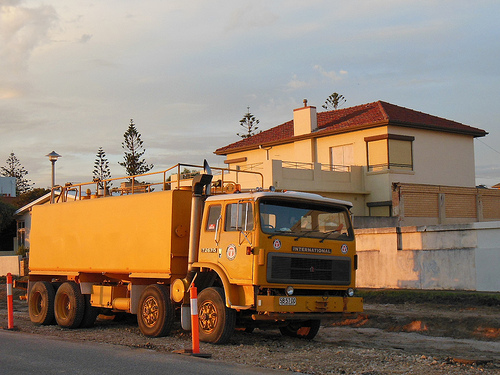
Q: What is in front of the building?
A: A truck.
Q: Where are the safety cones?
A: Next to the truck.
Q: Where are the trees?
A: Behind the house.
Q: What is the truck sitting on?
A: Gravel.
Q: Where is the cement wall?
A: Behind the truck.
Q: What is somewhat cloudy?
A: The sky.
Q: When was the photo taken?
A: Sunset.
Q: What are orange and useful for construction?
A: Safety markers.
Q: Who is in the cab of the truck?
A: No one is in the cab.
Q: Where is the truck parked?
A: On the gravel.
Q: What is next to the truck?
A: The road.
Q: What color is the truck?
A: Yellow.